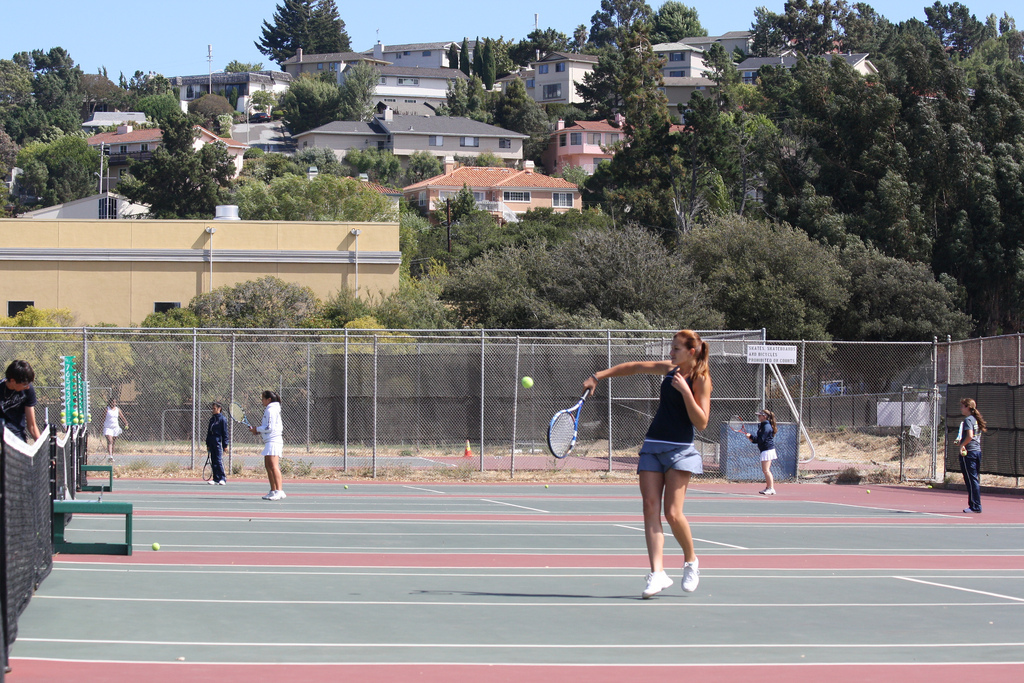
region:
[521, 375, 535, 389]
Tennis ball that is in mid play.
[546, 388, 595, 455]
Tennis racket the front lady is playing with.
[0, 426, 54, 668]
Net that the main woman is playing over.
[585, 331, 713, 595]
Closest girl playing tennis in gray shorts.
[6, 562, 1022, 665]
The tennis court the first girl is playing on.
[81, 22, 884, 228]
Community of houses on the hill top in the back ground.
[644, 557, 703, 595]
The bright white shoes the girl is wearing.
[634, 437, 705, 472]
Gray fitness shorts the first girl is wearing.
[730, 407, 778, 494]
Girl in a blue jacket playing in the back ground.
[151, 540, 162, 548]
Miscellaneous tennis ball on one of the courts.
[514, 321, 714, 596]
Girl hitting tennis ball.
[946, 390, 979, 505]
Girl standing on tennis court.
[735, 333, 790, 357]
White sign hanging on fence.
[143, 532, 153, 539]
Yellow tennis ball on court.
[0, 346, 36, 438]
Boy next to tennis net.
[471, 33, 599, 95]
White house on top of hill.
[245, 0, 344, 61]
Tree on top of hill.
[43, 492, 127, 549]
Green bench on tennis court.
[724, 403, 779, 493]
Girl in white skirt playing tennis.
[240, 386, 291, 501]
girl dressed in white playing tennis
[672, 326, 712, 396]
girls red hair in a pony tail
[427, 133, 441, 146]
window on a house on a hill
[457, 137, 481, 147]
window on a house on a hill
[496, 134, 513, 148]
window on a house on a hill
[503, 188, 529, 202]
window on a house on a hill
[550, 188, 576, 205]
window on a house on a hill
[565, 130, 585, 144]
window on a house on a hill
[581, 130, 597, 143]
window on a house on a hill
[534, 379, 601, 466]
blue and white tennis racquet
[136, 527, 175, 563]
green ball laying on ground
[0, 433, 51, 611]
black mesh tennis netting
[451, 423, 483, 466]
orange and white safety cone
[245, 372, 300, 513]
person in white clothing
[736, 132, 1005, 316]
tree covered in green leaves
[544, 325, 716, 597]
Woman swinging a tennis racket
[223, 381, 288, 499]
Woman holding a tennis racket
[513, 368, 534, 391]
Tennis ball in the air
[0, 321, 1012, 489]
Gate at the edge of a tennis court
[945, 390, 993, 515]
Woman standing on a tennis court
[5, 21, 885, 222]
Houses on a hillside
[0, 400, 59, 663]
Net on a tennis court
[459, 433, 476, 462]
Orange cone at the edge of a tennis court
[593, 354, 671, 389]
the arm of the tennis player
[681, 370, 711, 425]
the arm of the tennis player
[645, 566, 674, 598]
the white tennis shoe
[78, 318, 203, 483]
a chain link fence with metal posts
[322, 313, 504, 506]
a chain link fence with metal posts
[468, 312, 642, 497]
a chain link fence with metal posts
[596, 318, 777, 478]
a chain link fence with metal posts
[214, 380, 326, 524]
a person holding a tennis racket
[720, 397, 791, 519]
a person holding a tennis racket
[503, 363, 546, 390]
a green tennis ball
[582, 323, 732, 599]
woman wearing black tank top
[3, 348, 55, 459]
boy wearing black shirt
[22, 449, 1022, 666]
green tennis courts with white lines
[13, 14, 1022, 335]
green trees behind the tennis courts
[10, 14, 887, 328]
houses behind the tennis courts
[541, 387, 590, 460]
a blue and white tennis racket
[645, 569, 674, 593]
a white tennis shoe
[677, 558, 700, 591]
a white tennis shoe